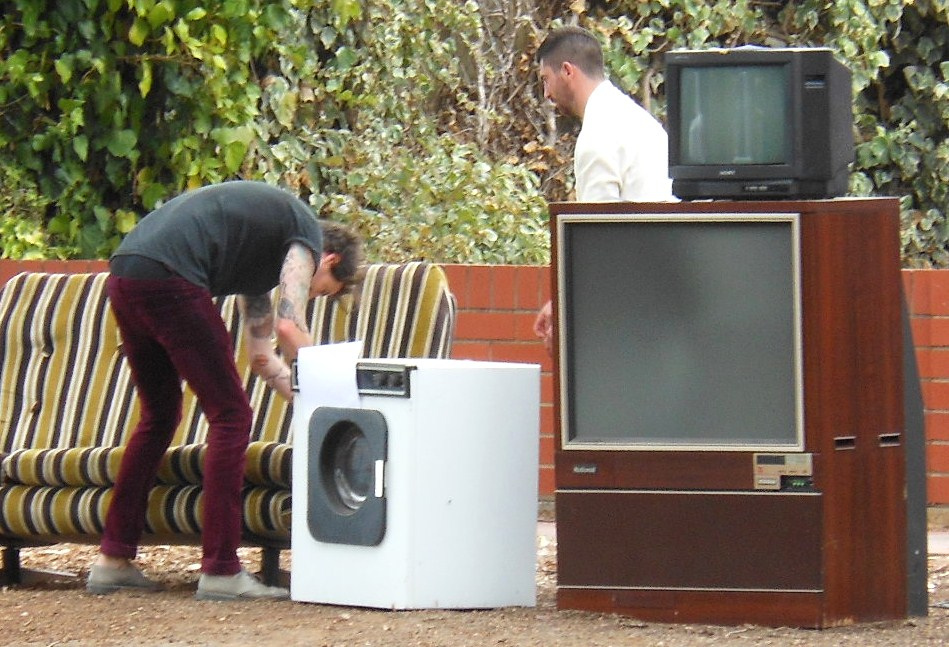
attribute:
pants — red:
[86, 229, 258, 586]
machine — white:
[275, 305, 580, 603]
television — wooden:
[526, 175, 910, 632]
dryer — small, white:
[267, 317, 618, 620]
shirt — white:
[556, 84, 662, 247]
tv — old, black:
[647, 22, 855, 206]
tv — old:
[528, 176, 926, 636]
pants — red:
[90, 248, 260, 568]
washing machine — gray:
[278, 333, 543, 636]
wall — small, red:
[404, 245, 581, 446]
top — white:
[554, 79, 729, 242]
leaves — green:
[24, 15, 267, 320]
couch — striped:
[2, 255, 460, 581]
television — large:
[544, 196, 933, 625]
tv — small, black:
[654, 46, 861, 206]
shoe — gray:
[188, 564, 296, 607]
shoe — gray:
[85, 559, 167, 600]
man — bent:
[79, 170, 375, 599]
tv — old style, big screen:
[547, 196, 900, 629]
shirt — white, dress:
[566, 75, 672, 206]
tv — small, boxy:
[665, 43, 865, 196]